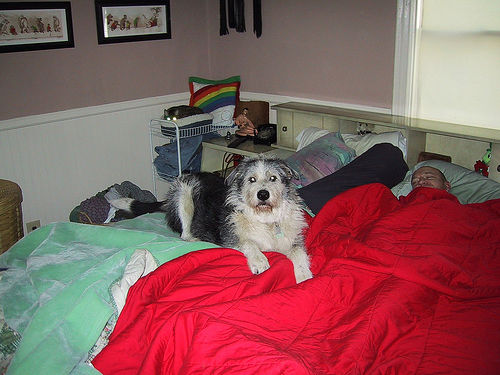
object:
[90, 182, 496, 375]
blanket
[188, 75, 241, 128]
pillow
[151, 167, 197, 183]
baskets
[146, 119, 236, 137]
basket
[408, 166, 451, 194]
head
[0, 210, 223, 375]
blanket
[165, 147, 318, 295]
dog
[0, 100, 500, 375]
bed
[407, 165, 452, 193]
man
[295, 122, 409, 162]
pillows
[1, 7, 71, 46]
paintings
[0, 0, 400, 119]
wall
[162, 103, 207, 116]
cat